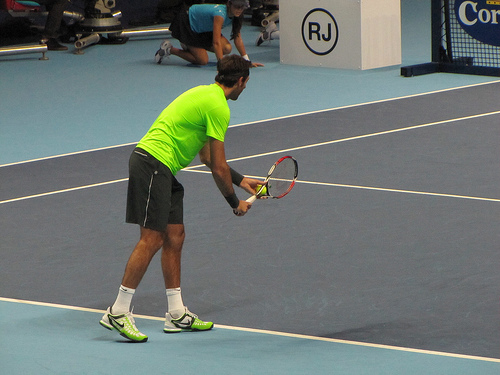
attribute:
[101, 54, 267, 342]
tennis player — male, competitive, serving, man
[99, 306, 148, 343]
shoe — green, white, black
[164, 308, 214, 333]
shoe — green, white, black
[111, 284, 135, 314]
sock — white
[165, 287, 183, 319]
sock — white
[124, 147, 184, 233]
shorts — black, lined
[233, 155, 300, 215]
tennis racket — red, white, blue, black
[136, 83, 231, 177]
shirt — green, bright, yellow-green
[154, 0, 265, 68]
ball girl — kneeling, crouching, waiting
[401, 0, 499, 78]
net — black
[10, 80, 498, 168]
baseline — white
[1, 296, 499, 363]
baseline — white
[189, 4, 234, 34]
t-shirt — blue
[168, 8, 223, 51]
skirt — black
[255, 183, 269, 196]
tennis ball — green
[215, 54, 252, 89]
hair — black